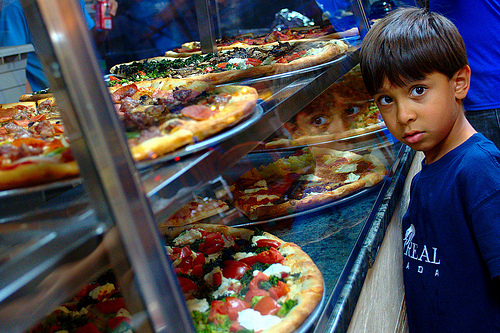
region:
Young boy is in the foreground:
[350, 4, 499, 331]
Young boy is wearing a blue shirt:
[384, 130, 498, 332]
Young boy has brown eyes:
[356, 68, 447, 120]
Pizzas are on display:
[0, 29, 406, 331]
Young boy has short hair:
[346, 1, 473, 97]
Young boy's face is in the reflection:
[255, 40, 383, 186]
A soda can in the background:
[87, 0, 117, 35]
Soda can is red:
[94, 2, 119, 35]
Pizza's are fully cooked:
[5, 21, 392, 331]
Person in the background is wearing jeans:
[466, 99, 499, 156]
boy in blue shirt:
[360, 8, 481, 249]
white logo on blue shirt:
[392, 216, 452, 288]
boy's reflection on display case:
[286, 75, 363, 164]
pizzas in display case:
[200, 31, 334, 142]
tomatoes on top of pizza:
[224, 237, 279, 279]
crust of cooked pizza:
[224, 85, 269, 117]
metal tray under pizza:
[215, 111, 262, 141]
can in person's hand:
[91, 0, 123, 40]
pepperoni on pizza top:
[172, 95, 221, 130]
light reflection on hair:
[379, 15, 440, 48]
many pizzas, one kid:
[1, 1, 498, 332]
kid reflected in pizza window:
[263, 40, 405, 242]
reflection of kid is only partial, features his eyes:
[264, 42, 424, 185]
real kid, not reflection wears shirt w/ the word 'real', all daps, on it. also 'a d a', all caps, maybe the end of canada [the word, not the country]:
[403, 239, 450, 281]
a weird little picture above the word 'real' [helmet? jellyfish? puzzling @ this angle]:
[402, 221, 419, 251]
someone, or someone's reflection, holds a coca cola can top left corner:
[88, 1, 120, 36]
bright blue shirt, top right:
[403, 0, 499, 115]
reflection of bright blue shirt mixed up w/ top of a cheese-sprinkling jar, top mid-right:
[307, 0, 415, 182]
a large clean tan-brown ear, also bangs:
[338, 57, 475, 110]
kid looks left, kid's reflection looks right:
[307, 78, 434, 135]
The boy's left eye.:
[374, 92, 400, 106]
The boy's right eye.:
[407, 83, 429, 97]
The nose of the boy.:
[397, 108, 415, 127]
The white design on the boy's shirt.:
[401, 217, 446, 282]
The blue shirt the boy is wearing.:
[411, 147, 496, 330]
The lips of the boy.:
[400, 127, 429, 145]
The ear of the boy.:
[448, 60, 475, 108]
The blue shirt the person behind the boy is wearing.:
[393, 4, 499, 109]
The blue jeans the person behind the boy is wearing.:
[457, 115, 499, 141]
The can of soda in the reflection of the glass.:
[87, 0, 122, 34]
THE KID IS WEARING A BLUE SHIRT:
[398, 125, 499, 330]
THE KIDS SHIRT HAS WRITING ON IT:
[396, 202, 447, 283]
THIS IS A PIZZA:
[0, 67, 273, 184]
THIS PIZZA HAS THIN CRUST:
[97, 33, 361, 93]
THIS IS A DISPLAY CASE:
[0, 1, 422, 331]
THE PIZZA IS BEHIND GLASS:
[0, 0, 427, 330]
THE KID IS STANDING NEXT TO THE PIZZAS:
[1, 22, 403, 329]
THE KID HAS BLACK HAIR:
[354, 5, 489, 110]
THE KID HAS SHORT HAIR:
[355, 6, 471, 102]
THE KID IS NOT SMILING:
[350, 7, 497, 330]